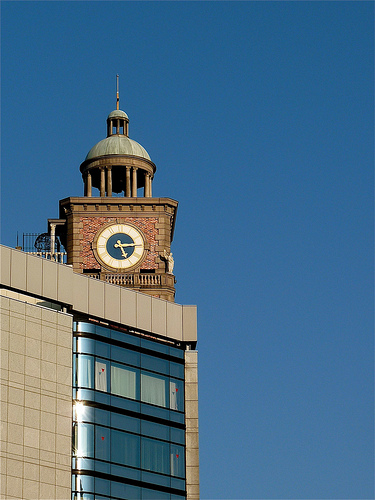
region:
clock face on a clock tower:
[92, 224, 143, 270]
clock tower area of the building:
[57, 69, 173, 300]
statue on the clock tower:
[162, 248, 177, 274]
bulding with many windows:
[3, 243, 198, 498]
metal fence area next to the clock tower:
[19, 230, 66, 262]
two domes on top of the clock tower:
[82, 108, 152, 165]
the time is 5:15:
[94, 221, 144, 268]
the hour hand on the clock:
[116, 240, 126, 257]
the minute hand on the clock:
[115, 242, 142, 247]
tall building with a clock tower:
[0, 74, 198, 495]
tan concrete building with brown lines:
[3, 299, 69, 496]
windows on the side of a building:
[84, 356, 179, 411]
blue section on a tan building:
[64, 313, 189, 495]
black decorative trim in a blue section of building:
[66, 323, 183, 371]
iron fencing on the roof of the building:
[5, 224, 69, 259]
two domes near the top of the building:
[77, 107, 157, 176]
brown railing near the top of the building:
[69, 267, 176, 295]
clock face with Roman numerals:
[94, 223, 146, 271]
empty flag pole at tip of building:
[112, 70, 121, 107]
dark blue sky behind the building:
[4, 6, 236, 291]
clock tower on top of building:
[61, 71, 196, 305]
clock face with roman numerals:
[91, 219, 149, 278]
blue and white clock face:
[92, 217, 151, 277]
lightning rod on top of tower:
[107, 68, 127, 114]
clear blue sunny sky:
[0, 2, 369, 488]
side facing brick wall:
[69, 202, 170, 283]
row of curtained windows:
[76, 352, 185, 417]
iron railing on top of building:
[11, 223, 67, 256]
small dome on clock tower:
[105, 107, 129, 123]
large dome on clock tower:
[76, 133, 159, 180]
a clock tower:
[60, 38, 201, 303]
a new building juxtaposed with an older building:
[0, 60, 257, 488]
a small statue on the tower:
[158, 239, 182, 280]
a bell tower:
[53, 89, 173, 204]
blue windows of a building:
[72, 324, 192, 498]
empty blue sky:
[211, 4, 372, 497]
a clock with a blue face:
[90, 217, 153, 268]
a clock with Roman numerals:
[84, 216, 157, 275]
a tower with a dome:
[54, 64, 201, 307]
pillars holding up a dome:
[82, 157, 176, 197]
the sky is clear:
[171, 75, 254, 195]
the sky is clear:
[256, 368, 357, 475]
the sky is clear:
[236, 353, 327, 496]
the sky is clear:
[237, 293, 352, 394]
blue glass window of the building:
[78, 342, 191, 497]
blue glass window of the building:
[75, 413, 198, 488]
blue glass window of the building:
[73, 340, 176, 432]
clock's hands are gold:
[93, 224, 173, 283]